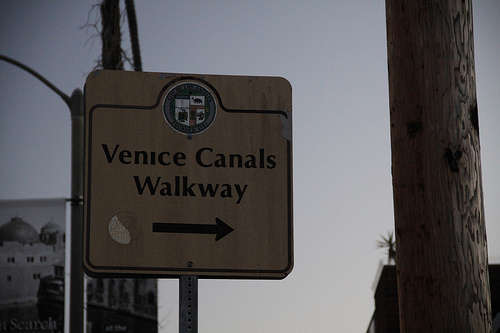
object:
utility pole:
[385, 4, 496, 331]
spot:
[403, 113, 424, 139]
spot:
[445, 145, 464, 174]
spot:
[464, 100, 487, 135]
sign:
[79, 68, 296, 278]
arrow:
[149, 216, 235, 242]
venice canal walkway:
[101, 138, 281, 209]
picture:
[1, 216, 68, 317]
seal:
[163, 81, 217, 132]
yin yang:
[109, 209, 145, 245]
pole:
[175, 273, 202, 331]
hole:
[188, 273, 193, 281]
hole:
[185, 309, 197, 316]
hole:
[188, 293, 196, 300]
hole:
[185, 303, 194, 312]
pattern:
[451, 12, 471, 95]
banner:
[1, 196, 66, 332]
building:
[368, 253, 500, 331]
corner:
[367, 251, 402, 298]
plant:
[379, 229, 401, 258]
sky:
[3, 4, 497, 332]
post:
[68, 81, 88, 332]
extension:
[1, 51, 71, 110]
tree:
[93, 2, 129, 77]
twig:
[80, 4, 105, 43]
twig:
[84, 51, 112, 70]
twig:
[117, 4, 135, 75]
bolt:
[186, 260, 195, 269]